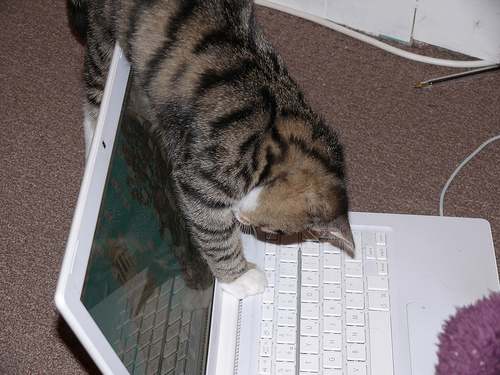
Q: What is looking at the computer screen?
A: The cat.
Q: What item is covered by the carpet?
A: The floor.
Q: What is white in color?
A: The keyboard of the laptop.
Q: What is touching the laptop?
A: The cat.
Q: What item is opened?
A: The lid of the laptop.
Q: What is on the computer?
A: The white keyboard.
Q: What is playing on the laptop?
A: The cat.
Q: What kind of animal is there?
A: Cat.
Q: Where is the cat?
A: Next to laptop.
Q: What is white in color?
A: Keyboard.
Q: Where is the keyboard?
A: Under cat.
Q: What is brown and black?
A: Cat.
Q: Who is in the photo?
A: No people.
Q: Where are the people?
A: None in photo.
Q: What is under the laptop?
A: The rug.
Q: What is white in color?
A: The cord.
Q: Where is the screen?
A: Next to cat.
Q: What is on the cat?
A: Black stripes.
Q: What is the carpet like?
A: Brown.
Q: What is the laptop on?
A: The brown carpet.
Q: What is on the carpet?
A: White wire.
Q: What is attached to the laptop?
A: A white cord.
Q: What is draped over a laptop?
A: A cat.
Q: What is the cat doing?
A: Playing with the laptop.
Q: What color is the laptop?
A: White.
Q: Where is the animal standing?
A: Keyboard.